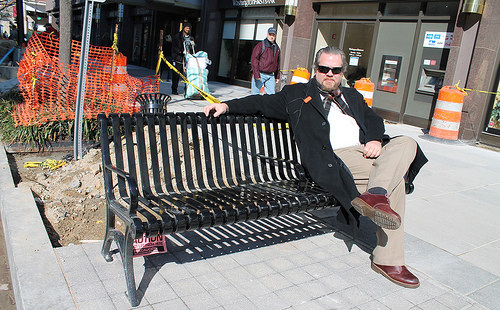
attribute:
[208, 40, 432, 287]
man — sitting, dapper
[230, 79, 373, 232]
coat — black, red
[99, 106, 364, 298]
bench — metal, black, park bench, wrought iron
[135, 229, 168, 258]
paper — pink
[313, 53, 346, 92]
face — man's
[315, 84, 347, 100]
neck — man's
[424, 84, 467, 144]
safety cone — large, white, orange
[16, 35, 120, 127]
net — orange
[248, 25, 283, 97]
man — walking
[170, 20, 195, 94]
man — wearing black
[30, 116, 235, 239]
pile — dirt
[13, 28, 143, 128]
barricade fencing — up, orange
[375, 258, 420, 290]
shoe — red, dress, casual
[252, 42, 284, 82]
jacket — red, purple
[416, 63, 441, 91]
atm machine — here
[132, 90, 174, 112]
trash can — black, metal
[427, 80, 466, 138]
cone — orange, white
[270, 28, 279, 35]
cap — blue, black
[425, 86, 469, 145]
construction barrel — yellow, white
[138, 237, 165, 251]
writing — black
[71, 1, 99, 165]
sign pole — metal, silver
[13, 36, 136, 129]
fencing — orange, plastic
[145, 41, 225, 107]
caution tape — here, yellow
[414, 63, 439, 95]
atm kiosk — here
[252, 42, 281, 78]
windbreaker — maroon